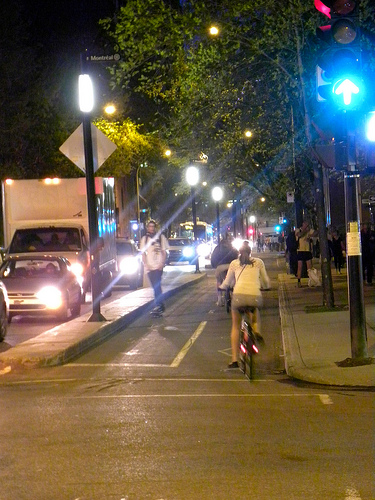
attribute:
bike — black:
[234, 322, 272, 380]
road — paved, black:
[63, 349, 337, 495]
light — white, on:
[61, 73, 110, 114]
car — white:
[6, 256, 77, 324]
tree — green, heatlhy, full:
[152, 23, 313, 186]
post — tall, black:
[67, 76, 120, 340]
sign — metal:
[59, 120, 120, 177]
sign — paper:
[340, 220, 361, 387]